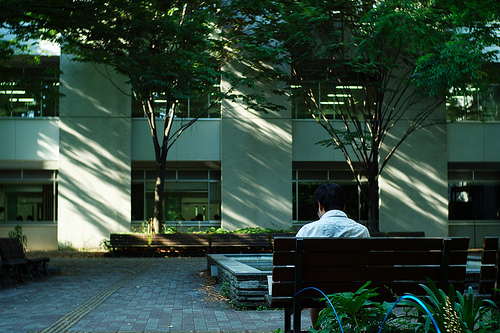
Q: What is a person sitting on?
A: On a bench.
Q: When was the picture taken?
A: Daytime.